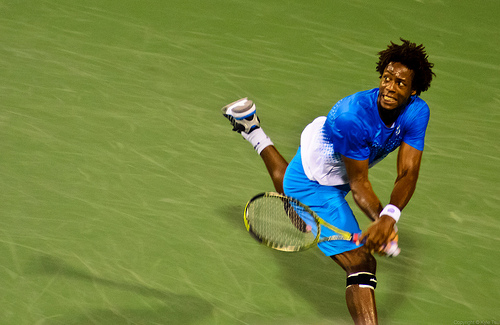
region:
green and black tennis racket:
[240, 188, 402, 260]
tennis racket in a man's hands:
[243, 186, 405, 258]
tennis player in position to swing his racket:
[218, 36, 438, 323]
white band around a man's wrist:
[380, 200, 401, 220]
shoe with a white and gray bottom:
[220, 95, 270, 134]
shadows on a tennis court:
[25, 193, 422, 320]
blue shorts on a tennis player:
[281, 146, 380, 257]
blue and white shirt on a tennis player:
[298, 84, 431, 186]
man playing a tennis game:
[218, 35, 441, 323]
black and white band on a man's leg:
[343, 271, 378, 288]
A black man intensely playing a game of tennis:
[200, 15, 488, 320]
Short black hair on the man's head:
[372, 35, 435, 91]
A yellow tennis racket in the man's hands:
[231, 190, 392, 257]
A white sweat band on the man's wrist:
[371, 200, 406, 222]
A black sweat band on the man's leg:
[344, 266, 381, 294]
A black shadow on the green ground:
[39, 243, 250, 323]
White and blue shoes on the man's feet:
[217, 88, 268, 134]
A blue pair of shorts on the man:
[277, 145, 381, 266]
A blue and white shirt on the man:
[296, 92, 442, 199]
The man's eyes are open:
[377, 73, 407, 90]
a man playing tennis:
[190, 29, 457, 323]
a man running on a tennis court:
[211, 25, 444, 320]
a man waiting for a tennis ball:
[216, 20, 437, 324]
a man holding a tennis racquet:
[242, 187, 408, 267]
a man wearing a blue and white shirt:
[301, 86, 436, 196]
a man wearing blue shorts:
[277, 145, 374, 257]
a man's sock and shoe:
[219, 93, 279, 158]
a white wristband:
[377, 200, 404, 221]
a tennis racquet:
[242, 187, 404, 261]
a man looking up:
[213, 35, 455, 324]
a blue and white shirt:
[275, 75, 402, 192]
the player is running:
[211, 21, 446, 310]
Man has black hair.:
[383, 41, 450, 106]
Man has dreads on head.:
[375, 43, 450, 100]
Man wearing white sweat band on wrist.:
[377, 197, 414, 239]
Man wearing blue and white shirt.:
[308, 117, 373, 168]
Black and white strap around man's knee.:
[338, 259, 398, 309]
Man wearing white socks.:
[235, 135, 286, 152]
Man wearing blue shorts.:
[286, 149, 337, 240]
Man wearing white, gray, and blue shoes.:
[217, 98, 252, 128]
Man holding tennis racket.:
[275, 189, 406, 263]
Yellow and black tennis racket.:
[217, 144, 409, 305]